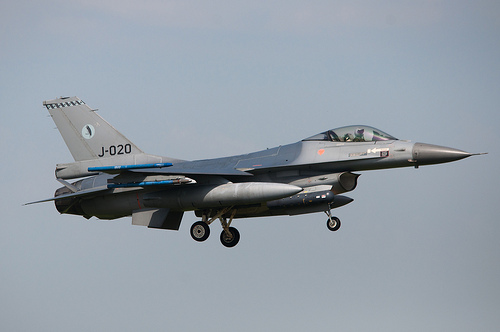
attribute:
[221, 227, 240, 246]
wheels — black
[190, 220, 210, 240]
wheels — black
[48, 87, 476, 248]
plane — enemies, looking , flying , very fast, dropping bombs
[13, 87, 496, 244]
plane — military aircraft, air,  military,  military fighter,  jet aircraft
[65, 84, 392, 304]
aircraft — military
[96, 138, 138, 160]
lettering — black , J-020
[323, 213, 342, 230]
black/white tire — black, white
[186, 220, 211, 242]
black/white tire — white, black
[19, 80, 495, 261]
jet — black, grey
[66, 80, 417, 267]
plane — loaded , ordinance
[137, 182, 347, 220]
fuel — jet 